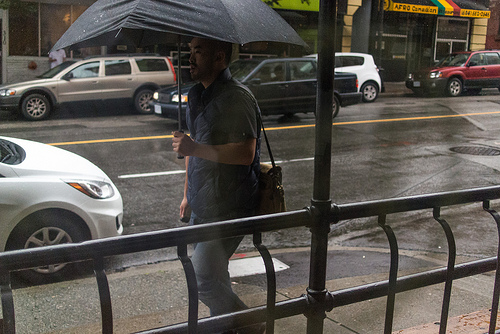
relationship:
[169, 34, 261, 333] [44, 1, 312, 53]
man holding umbrella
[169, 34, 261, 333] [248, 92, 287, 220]
man has a bag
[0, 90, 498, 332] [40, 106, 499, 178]
road has lines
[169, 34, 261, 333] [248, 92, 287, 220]
man wearing bag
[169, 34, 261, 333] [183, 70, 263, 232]
man wearing tshirt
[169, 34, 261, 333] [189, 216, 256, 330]
man wearing pants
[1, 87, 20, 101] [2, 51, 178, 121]
one headlight on vehicle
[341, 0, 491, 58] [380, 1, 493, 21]
store has colorful awning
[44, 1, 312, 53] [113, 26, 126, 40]
umbrella has broken part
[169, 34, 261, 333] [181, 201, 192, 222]
man holding phone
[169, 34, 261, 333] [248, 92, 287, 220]
man carrying a bag